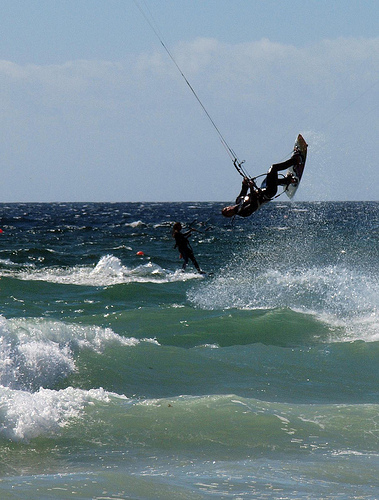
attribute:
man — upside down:
[219, 146, 303, 221]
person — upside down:
[170, 219, 207, 275]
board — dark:
[283, 119, 323, 208]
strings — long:
[129, 1, 248, 165]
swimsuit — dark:
[233, 158, 296, 219]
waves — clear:
[4, 199, 375, 494]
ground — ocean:
[256, 138, 268, 167]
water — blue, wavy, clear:
[5, 200, 376, 491]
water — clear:
[3, 198, 374, 332]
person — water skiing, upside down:
[211, 146, 307, 230]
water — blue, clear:
[7, 202, 373, 349]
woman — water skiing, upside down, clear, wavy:
[171, 216, 206, 275]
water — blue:
[60, 268, 338, 322]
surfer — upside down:
[219, 146, 300, 218]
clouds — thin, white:
[0, 35, 377, 200]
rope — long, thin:
[147, 31, 235, 153]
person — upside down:
[167, 211, 205, 264]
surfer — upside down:
[219, 147, 307, 220]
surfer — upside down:
[219, 154, 298, 218]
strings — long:
[138, 7, 248, 175]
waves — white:
[321, 209, 353, 242]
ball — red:
[134, 245, 146, 258]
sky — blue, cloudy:
[3, 5, 361, 205]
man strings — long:
[231, 180, 255, 198]